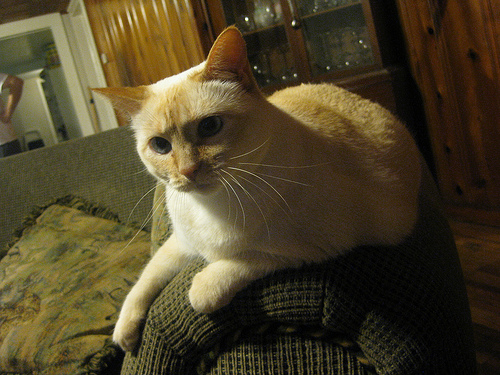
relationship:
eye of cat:
[138, 122, 177, 159] [64, 40, 426, 327]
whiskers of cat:
[119, 181, 216, 271] [60, 40, 432, 285]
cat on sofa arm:
[82, 22, 427, 353] [119, 175, 464, 371]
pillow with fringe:
[2, 190, 177, 374] [3, 189, 148, 259]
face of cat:
[137, 104, 235, 196] [112, 22, 427, 356]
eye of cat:
[146, 135, 173, 155] [82, 22, 427, 353]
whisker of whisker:
[229, 165, 296, 215] [220, 175, 247, 232]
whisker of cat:
[228, 134, 272, 158] [82, 22, 427, 353]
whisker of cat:
[220, 175, 247, 232] [82, 22, 427, 353]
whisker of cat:
[221, 167, 251, 200] [82, 22, 427, 353]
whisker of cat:
[234, 173, 296, 228] [82, 22, 427, 353]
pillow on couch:
[2, 190, 177, 374] [0, 156, 460, 373]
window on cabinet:
[231, 8, 386, 75] [201, 4, 413, 99]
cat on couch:
[82, 22, 427, 353] [0, 126, 479, 374]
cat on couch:
[82, 22, 427, 353] [11, 124, 440, 334]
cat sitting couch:
[82, 22, 427, 353] [1, 112, 472, 374]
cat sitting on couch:
[82, 22, 427, 353] [126, 80, 498, 374]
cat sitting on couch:
[82, 22, 427, 353] [1, 112, 472, 374]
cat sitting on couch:
[82, 22, 427, 353] [3, 133, 473, 363]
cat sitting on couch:
[112, 22, 427, 356] [3, 133, 473, 363]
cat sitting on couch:
[82, 22, 427, 353] [275, 241, 464, 373]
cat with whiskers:
[82, 22, 427, 353] [96, 135, 336, 255]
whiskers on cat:
[96, 135, 336, 255] [82, 22, 427, 353]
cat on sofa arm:
[112, 22, 427, 356] [141, 189, 473, 374]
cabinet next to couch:
[82, 2, 440, 197] [0, 126, 479, 374]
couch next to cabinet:
[0, 126, 479, 374] [82, 2, 440, 197]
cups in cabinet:
[240, 3, 375, 83] [205, 4, 395, 91]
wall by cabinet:
[106, 17, 491, 207] [217, 0, 431, 88]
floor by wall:
[457, 187, 488, 262] [408, 5, 485, 195]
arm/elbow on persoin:
[3, 65, 30, 132] [1, 67, 29, 160]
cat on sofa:
[82, 22, 427, 353] [9, 61, 476, 373]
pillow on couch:
[2, 190, 177, 374] [0, 126, 479, 374]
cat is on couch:
[82, 22, 427, 353] [1, 112, 472, 374]